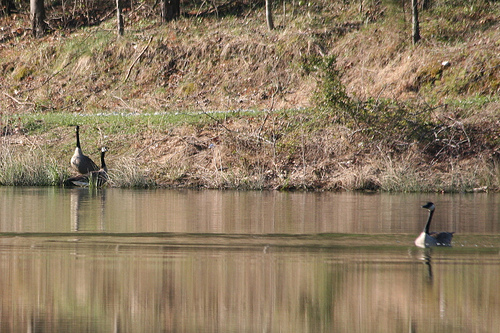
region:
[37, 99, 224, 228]
Ducks by the water.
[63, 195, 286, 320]
Reflections in the water.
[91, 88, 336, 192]
Grass on the shore.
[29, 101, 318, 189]
Green grass on the shore.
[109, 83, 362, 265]
Dead grass on the shore.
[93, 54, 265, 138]
Road on the hill.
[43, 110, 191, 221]
Two geese on the ground.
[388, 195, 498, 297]
one goose in the water.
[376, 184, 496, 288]
one goose.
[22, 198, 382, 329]
This is a body of water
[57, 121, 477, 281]
There are three ducks in the water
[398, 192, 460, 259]
This duck is swimming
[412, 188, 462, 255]
The left side of this duck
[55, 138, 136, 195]
The right side of this duck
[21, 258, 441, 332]
Many things are reflected in the water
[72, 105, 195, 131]
A patch of green grass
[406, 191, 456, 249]
A goose that is in the water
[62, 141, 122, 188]
A goose in the water by the shore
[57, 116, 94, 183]
A goose who is on the land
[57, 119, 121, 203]
Two geese standing together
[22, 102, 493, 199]
The shore line near the lake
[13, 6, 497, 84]
The tree trunks behind the lake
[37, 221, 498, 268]
The ripples in the lakes surface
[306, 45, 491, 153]
A small tree at the edge of the lake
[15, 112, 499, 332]
A lake with geese in it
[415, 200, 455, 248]
A goose in the water.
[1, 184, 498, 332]
Brown water with reflections on it.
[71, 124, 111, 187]
Two geese on shore.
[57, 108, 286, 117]
Slightly visible white gravel up the hill.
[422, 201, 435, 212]
Black and white head of a swan.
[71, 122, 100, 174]
Larger goose on land.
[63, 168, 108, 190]
Body of a smaller swan on land.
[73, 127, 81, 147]
Long black neck of a swan on land the most.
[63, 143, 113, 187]
The goose on land but nearest to the water.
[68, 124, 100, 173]
The goose most on land.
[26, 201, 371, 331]
The water is very calm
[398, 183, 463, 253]
The swan is in the water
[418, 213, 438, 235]
The neck of the swan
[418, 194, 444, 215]
The head of the swan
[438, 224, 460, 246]
The back of the swan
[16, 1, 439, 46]
The tree trunks are the color brown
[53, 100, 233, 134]
The area of grass is green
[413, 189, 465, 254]
The swan is black and gray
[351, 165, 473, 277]
bird in the water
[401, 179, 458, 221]
head of the bird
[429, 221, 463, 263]
back of the bird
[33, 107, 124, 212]
two birds next to water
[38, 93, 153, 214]
two birds with feathers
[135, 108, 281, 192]
brown grass next to water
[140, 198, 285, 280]
ripples in the water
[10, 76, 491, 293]
three birds in and near water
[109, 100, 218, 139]
green grass near birds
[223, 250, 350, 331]
reflection in the water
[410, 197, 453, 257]
The duck on the right.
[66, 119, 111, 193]
The two ducks on the left.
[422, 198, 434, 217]
The head of the duck.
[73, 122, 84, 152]
The long neck of the duck.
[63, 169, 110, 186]
The body of the duck.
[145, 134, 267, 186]
The brown brush in the back.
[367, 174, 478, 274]
floating bird in water